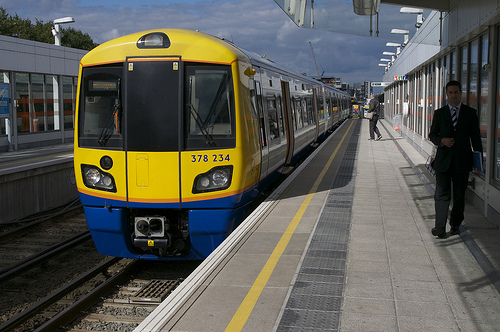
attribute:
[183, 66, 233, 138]
window — glass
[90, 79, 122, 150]
window — glass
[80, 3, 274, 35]
sky — cloudy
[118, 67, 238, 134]
window — glass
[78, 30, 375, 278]
train — yellow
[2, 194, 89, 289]
train tracks — empty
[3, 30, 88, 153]
building — on left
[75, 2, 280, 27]
sky — cloudy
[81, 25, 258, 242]
train — yellow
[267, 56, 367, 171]
window — glass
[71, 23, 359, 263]
train — yellow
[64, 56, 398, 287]
train — yellow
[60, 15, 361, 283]
train — yellow